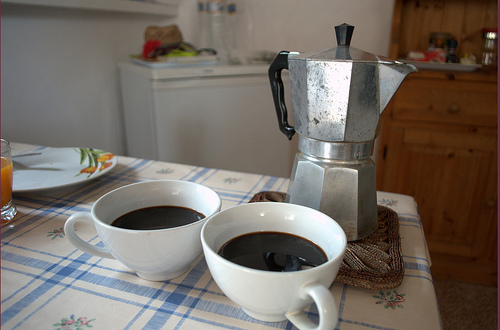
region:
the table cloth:
[28, 262, 89, 312]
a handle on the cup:
[64, 222, 88, 250]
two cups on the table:
[65, 175, 350, 324]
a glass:
[3, 146, 23, 217]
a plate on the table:
[48, 162, 78, 191]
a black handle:
[266, 71, 290, 107]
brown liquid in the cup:
[245, 238, 297, 264]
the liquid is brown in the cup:
[136, 209, 161, 226]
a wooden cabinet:
[396, 139, 463, 184]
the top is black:
[331, 19, 358, 45]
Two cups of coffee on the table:
[63, 174, 350, 329]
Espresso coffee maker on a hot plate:
[251, 17, 413, 289]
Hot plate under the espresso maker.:
[246, 185, 396, 296]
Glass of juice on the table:
[0, 140, 12, 217]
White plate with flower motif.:
[5, 140, 115, 190]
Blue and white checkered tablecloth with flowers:
[0, 135, 440, 325]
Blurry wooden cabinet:
[376, 0, 492, 290]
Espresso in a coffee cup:
[61, 175, 217, 282]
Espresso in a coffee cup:
[200, 199, 351, 327]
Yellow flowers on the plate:
[75, 142, 115, 179]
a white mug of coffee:
[59, 177, 219, 286]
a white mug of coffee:
[200, 200, 344, 329]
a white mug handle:
[65, 211, 109, 262]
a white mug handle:
[286, 284, 339, 329]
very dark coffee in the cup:
[109, 204, 202, 231]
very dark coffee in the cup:
[216, 229, 328, 274]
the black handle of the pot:
[266, 49, 297, 142]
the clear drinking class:
[1, 137, 14, 221]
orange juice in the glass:
[1, 158, 11, 210]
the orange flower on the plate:
[78, 148, 95, 175]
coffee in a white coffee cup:
[57, 178, 222, 283]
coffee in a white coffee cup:
[201, 202, 350, 328]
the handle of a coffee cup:
[61, 202, 108, 268]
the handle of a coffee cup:
[284, 282, 344, 328]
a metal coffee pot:
[256, 8, 421, 259]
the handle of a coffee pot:
[259, 44, 308, 156]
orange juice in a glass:
[0, 125, 22, 238]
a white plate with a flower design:
[13, 140, 120, 201]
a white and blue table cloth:
[20, 245, 95, 326]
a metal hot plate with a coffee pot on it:
[259, 17, 412, 299]